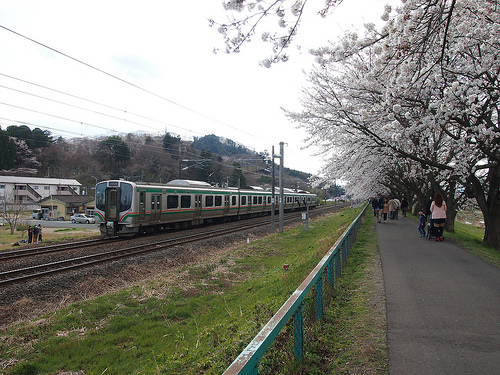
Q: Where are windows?
A: On the train.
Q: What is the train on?
A: Train tracks.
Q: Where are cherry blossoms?
A: On trees.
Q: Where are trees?
A: Along walkway.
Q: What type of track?
A: Train.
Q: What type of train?
A: Electric.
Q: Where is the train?
A: On tracks.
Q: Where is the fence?
A: Beside path.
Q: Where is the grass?
A: Beside fence.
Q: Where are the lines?
A: Above train.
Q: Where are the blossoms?
A: On trees.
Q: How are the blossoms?
A: Full.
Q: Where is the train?
A: Railway.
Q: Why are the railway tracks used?
A: Trains to travel.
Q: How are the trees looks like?
A: White blossoming flowers.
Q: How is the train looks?
A: Green and orange stripes.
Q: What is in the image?
A: Railroad track.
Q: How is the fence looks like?
A: Metal.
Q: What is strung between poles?
A: Power lines.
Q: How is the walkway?
A: Paved.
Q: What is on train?
A: Stripes.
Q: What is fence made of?
A: Metal.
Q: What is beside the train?
A: Rail.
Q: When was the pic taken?
A: During the day.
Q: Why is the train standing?
A: To pick people.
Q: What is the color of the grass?
A: Green.